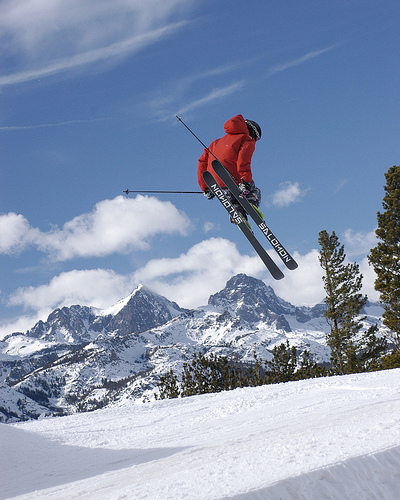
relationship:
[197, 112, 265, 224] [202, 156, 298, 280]
man has on person's ski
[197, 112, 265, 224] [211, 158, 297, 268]
man has on ski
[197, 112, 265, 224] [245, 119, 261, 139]
man wearing hat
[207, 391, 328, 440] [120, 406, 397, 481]
ski tracks in snow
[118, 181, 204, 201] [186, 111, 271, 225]
pole of person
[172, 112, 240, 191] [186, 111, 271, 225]
pole of person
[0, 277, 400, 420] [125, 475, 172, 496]
hill in snow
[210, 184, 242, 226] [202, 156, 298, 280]
writing in person's ski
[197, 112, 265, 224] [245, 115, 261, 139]
man wearing hat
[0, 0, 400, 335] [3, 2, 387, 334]
cloud in sky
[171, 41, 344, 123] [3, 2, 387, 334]
cloud in sky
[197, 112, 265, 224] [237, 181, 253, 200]
man wears glove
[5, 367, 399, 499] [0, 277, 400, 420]
snow covered hill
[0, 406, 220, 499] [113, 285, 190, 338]
shadow on hill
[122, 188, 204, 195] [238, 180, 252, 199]
pole in hand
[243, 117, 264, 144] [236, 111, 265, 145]
goggles on head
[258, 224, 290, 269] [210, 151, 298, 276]
label on ski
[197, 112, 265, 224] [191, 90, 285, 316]
man doing jump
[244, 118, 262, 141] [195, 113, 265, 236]
head of jumping skier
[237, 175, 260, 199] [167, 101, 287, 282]
hand of skier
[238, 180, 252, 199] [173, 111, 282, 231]
hand of skier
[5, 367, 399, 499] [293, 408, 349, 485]
snow on ground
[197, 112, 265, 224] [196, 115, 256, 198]
man wearing a coat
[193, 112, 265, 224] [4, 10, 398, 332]
man skiing in air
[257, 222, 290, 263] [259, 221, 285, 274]
label on ski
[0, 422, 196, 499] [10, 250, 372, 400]
shadow on mountain